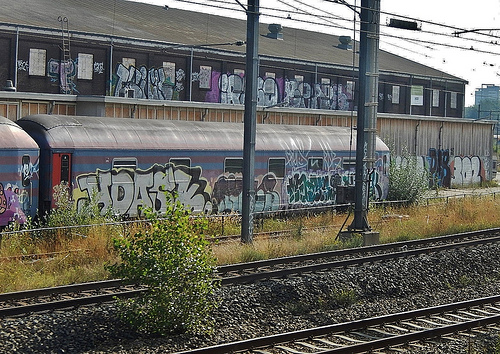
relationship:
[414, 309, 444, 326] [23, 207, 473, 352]
board between tracks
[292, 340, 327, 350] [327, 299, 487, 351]
wooden board between tracks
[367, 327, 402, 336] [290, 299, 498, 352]
board between tracks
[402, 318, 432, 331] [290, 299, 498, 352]
board between tracks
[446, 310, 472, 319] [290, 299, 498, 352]
board between tracks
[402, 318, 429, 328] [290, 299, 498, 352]
board between tracks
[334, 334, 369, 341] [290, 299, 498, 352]
board between tracks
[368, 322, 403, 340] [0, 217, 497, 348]
board between tracks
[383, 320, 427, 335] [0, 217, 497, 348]
wooden board between tracks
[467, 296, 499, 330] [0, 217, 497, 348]
board between tracks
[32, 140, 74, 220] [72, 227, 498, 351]
board on tracks